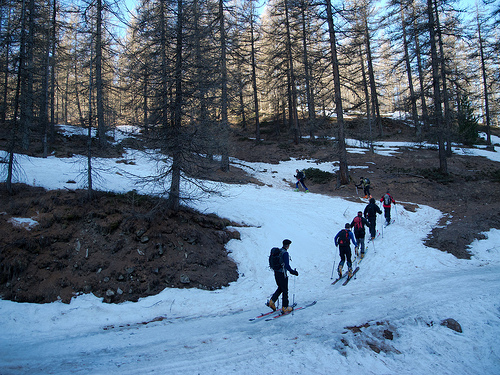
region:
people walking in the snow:
[210, 179, 413, 345]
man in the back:
[241, 241, 317, 318]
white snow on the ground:
[176, 298, 244, 342]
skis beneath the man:
[241, 292, 321, 336]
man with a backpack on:
[251, 231, 311, 302]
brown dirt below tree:
[82, 208, 184, 278]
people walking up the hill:
[251, 167, 406, 311]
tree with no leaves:
[128, 141, 232, 218]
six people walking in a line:
[244, 142, 424, 333]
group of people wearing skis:
[204, 147, 419, 320]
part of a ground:
[171, 262, 224, 324]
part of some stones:
[366, 317, 400, 343]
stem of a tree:
[162, 177, 196, 223]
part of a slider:
[248, 306, 263, 326]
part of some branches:
[186, 122, 228, 239]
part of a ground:
[433, 142, 469, 224]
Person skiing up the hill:
[358, 173, 373, 201]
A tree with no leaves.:
[131, 6, 237, 243]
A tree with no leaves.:
[84, 2, 128, 146]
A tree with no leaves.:
[367, 0, 462, 171]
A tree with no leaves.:
[305, 0, 381, 192]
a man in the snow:
[261, 235, 296, 320]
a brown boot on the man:
[277, 298, 297, 315]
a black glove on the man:
[288, 262, 300, 278]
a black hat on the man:
[280, 232, 295, 245]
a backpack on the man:
[264, 239, 283, 274]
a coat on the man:
[271, 245, 293, 279]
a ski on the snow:
[340, 257, 365, 287]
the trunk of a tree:
[163, 161, 193, 205]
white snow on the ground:
[0, 114, 499, 374]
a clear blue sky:
[1, 0, 496, 83]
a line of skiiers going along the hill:
[258, 177, 408, 320]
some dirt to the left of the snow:
[4, 185, 234, 292]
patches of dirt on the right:
[201, 123, 498, 240]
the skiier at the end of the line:
[263, 236, 302, 323]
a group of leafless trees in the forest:
[8, 6, 485, 153]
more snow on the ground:
[191, 186, 358, 290]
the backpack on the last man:
[265, 246, 282, 281]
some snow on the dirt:
[11, 210, 35, 230]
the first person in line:
[353, 175, 371, 197]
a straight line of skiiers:
[328, 193, 395, 293]